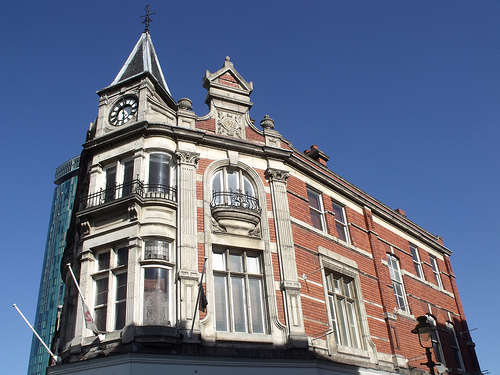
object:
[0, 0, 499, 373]
sky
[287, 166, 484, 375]
wall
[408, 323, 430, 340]
light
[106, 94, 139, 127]
clock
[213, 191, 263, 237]
balcony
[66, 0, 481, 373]
building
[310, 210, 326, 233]
window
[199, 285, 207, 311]
flag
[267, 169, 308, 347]
spire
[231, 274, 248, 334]
window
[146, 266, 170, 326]
window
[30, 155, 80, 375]
building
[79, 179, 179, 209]
railing